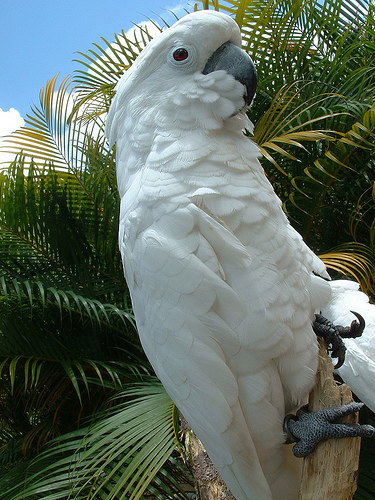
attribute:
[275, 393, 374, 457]
fingers — dark, black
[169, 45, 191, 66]
eye — bright, round, black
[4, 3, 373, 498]
trees — green, dark, bright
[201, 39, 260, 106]
beak — short, black, dark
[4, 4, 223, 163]
sky — clear, bright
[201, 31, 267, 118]
beak — black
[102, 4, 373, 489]
parrot — white, close, large, light, tall, looking